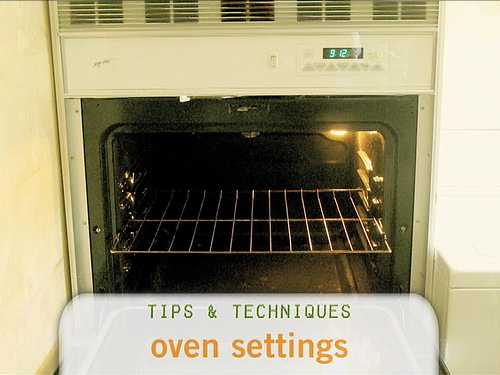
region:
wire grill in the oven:
[128, 174, 385, 258]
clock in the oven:
[313, 41, 364, 65]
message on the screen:
[124, 286, 366, 370]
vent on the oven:
[52, 5, 432, 28]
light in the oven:
[315, 121, 354, 146]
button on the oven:
[373, 65, 386, 76]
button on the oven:
[357, 61, 371, 75]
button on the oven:
[348, 62, 358, 73]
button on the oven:
[340, 63, 352, 75]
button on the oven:
[325, 61, 337, 75]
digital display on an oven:
[321, 44, 366, 60]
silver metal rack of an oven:
[100, 174, 399, 276]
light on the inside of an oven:
[323, 119, 356, 143]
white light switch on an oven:
[266, 47, 279, 72]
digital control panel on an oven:
[285, 38, 395, 79]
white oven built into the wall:
[34, 4, 449, 290]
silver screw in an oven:
[91, 224, 106, 234]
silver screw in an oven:
[395, 224, 410, 235]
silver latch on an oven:
[235, 102, 264, 119]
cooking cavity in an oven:
[107, 129, 390, 293]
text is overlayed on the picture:
[57, 285, 440, 374]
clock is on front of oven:
[317, 45, 367, 57]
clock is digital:
[320, 46, 366, 58]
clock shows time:
[320, 45, 367, 60]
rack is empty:
[110, 169, 390, 256]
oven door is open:
[50, 31, 451, 373]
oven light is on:
[322, 124, 354, 141]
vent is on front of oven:
[51, 0, 442, 27]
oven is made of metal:
[79, 97, 413, 294]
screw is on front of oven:
[397, 222, 409, 233]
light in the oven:
[330, 127, 346, 144]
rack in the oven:
[120, 179, 386, 256]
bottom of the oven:
[145, 215, 370, 290]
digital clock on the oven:
[323, 44, 363, 61]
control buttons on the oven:
[302, 59, 385, 74]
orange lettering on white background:
[148, 333, 348, 363]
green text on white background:
[148, 302, 358, 327]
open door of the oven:
[81, 305, 419, 374]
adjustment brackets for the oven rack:
[124, 158, 392, 260]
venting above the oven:
[67, 0, 425, 25]